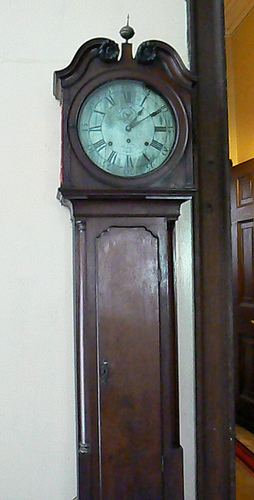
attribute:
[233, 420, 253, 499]
floor pattern — red, yellow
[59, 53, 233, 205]
clock — old, light, teal-colored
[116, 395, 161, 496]
door —  missing door 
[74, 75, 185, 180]
clock face —  old clock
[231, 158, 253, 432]
door — brown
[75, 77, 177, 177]
clock — opening , face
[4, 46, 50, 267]
wall — white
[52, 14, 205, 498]
grandfather clock — long, old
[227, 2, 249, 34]
border — ceiling 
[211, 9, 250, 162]
wall — white painted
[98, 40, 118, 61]
decoration — black, flower-shaped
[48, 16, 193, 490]
clock — brown, rectangular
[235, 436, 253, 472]
carpet — black piece  , red   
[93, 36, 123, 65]
rosettes — wood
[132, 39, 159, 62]
rosettes — wood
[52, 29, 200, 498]
clock — brown grandfather  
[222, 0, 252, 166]
wall — yellow painted 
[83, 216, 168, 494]
door — long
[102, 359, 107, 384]
handle — black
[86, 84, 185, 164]
clock — grandfather's 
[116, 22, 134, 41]
decoration — round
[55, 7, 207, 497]
clock — body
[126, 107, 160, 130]
hands — Clock 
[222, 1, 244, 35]
trimming — thick 